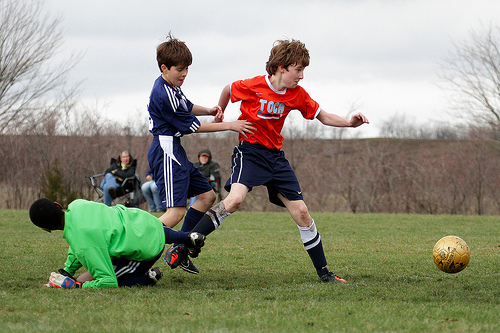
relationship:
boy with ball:
[185, 17, 344, 270] [426, 229, 485, 283]